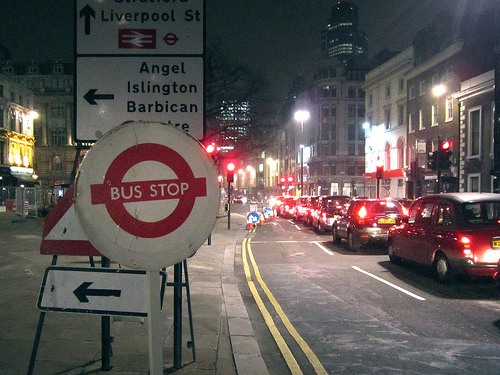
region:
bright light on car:
[353, 199, 372, 229]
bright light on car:
[455, 223, 480, 257]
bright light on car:
[405, 203, 420, 225]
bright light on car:
[306, 202, 317, 227]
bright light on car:
[296, 201, 309, 221]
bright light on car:
[291, 207, 300, 222]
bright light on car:
[279, 193, 298, 227]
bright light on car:
[277, 196, 287, 213]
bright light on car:
[268, 193, 279, 207]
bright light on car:
[395, 200, 420, 227]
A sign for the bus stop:
[79, 124, 222, 267]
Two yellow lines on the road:
[238, 232, 327, 374]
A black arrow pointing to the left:
[37, 267, 160, 317]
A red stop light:
[220, 158, 241, 229]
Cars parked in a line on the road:
[273, 194, 498, 284]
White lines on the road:
[280, 215, 425, 310]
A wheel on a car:
[430, 250, 452, 280]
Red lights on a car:
[352, 202, 410, 222]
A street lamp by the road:
[290, 106, 314, 195]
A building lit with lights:
[0, 77, 44, 215]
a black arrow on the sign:
[70, 281, 121, 302]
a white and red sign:
[72, 123, 221, 265]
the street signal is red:
[222, 160, 237, 183]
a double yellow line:
[239, 236, 326, 373]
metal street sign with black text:
[72, 3, 204, 141]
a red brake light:
[460, 236, 475, 250]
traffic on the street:
[270, 194, 490, 282]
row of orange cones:
[244, 206, 278, 229]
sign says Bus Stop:
[108, 177, 193, 202]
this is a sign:
[60, 101, 234, 373]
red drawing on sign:
[82, 114, 240, 305]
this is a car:
[389, 162, 493, 319]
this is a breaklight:
[432, 221, 480, 267]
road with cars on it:
[260, 162, 485, 306]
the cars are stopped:
[265, 168, 487, 333]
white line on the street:
[332, 252, 417, 317]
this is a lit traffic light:
[418, 122, 485, 212]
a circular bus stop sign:
[70, 118, 223, 273]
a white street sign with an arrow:
[41, 270, 154, 316]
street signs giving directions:
[75, 2, 205, 141]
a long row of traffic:
[274, 195, 497, 291]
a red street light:
[223, 160, 234, 232]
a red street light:
[438, 138, 452, 170]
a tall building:
[0, 77, 32, 167]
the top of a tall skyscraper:
[321, 3, 368, 63]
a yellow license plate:
[375, 218, 395, 223]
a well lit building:
[221, 95, 248, 140]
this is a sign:
[67, 135, 228, 295]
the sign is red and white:
[59, 118, 264, 312]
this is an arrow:
[54, 283, 126, 323]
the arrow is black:
[49, 255, 196, 350]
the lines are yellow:
[225, 245, 316, 341]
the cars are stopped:
[284, 141, 485, 291]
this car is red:
[407, 203, 494, 275]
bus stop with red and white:
[69, 116, 226, 278]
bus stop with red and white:
[63, 117, 227, 277]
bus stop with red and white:
[61, 110, 226, 281]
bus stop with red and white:
[58, 118, 227, 289]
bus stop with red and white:
[64, 113, 233, 283]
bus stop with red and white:
[60, 113, 238, 284]